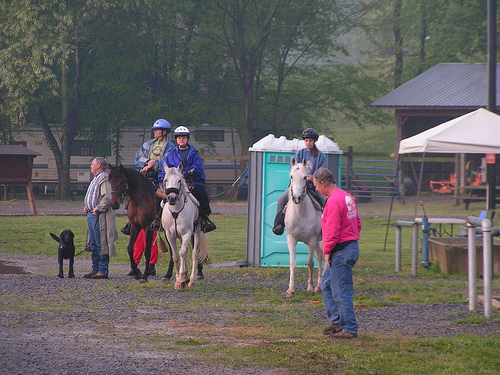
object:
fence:
[340, 157, 401, 204]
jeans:
[318, 239, 362, 335]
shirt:
[320, 187, 363, 255]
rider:
[120, 118, 180, 237]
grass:
[355, 340, 492, 374]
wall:
[0, 123, 245, 186]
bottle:
[245, 133, 344, 270]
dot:
[284, 156, 291, 163]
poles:
[480, 220, 495, 320]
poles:
[465, 218, 477, 310]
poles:
[409, 222, 420, 282]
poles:
[392, 218, 403, 273]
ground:
[0, 195, 499, 370]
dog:
[46, 229, 77, 280]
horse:
[106, 162, 205, 284]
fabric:
[163, 187, 181, 196]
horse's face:
[162, 167, 182, 206]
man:
[311, 166, 364, 339]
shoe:
[327, 330, 358, 339]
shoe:
[320, 322, 343, 336]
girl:
[270, 127, 327, 237]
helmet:
[301, 128, 319, 142]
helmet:
[173, 125, 191, 139]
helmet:
[150, 118, 172, 133]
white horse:
[281, 157, 327, 300]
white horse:
[159, 160, 208, 292]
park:
[2, 1, 496, 372]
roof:
[367, 62, 500, 115]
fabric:
[132, 227, 159, 265]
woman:
[148, 123, 217, 234]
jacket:
[157, 143, 207, 190]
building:
[368, 58, 498, 204]